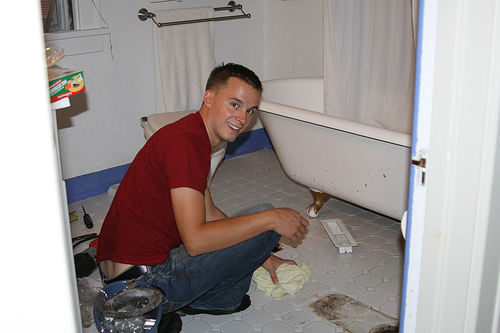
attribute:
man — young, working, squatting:
[91, 61, 309, 330]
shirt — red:
[99, 105, 212, 264]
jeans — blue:
[68, 205, 287, 319]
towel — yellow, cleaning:
[247, 259, 314, 303]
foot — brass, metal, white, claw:
[304, 186, 332, 222]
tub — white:
[249, 72, 412, 235]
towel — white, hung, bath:
[151, 6, 212, 118]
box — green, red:
[42, 70, 92, 101]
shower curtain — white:
[319, 2, 420, 139]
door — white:
[399, 3, 494, 331]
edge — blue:
[396, 0, 430, 331]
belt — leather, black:
[88, 264, 154, 284]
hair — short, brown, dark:
[204, 59, 265, 99]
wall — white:
[0, 6, 357, 179]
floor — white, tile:
[33, 139, 427, 329]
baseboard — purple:
[54, 127, 282, 208]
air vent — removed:
[317, 215, 357, 257]